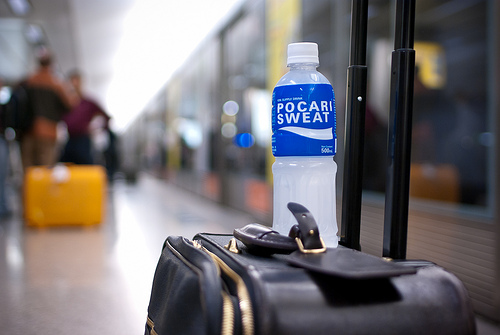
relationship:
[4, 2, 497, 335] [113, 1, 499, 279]
train station with train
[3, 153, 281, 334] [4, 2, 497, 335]
platform at train station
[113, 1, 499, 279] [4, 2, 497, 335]
train at train station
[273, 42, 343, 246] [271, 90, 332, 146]
water bottle with a label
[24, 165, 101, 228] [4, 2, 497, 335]
suitcase at train station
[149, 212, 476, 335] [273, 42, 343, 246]
suitcase with water bottle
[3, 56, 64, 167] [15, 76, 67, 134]
man with a jacket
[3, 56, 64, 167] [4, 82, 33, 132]
man carrying backpack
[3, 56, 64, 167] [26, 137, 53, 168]
man wearing pants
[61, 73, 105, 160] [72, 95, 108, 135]
person wearing shirt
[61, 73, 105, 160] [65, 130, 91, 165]
person wearing pants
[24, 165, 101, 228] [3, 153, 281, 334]
suitcase sitting on platform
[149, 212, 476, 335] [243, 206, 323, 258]
suitcase with handle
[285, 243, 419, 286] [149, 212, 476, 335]
tag on suitcase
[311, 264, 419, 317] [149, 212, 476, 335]
shadow on suitcase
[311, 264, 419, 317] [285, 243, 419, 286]
shadow from tag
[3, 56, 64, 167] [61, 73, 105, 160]
man talking to person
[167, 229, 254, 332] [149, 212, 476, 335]
zippers on suitcase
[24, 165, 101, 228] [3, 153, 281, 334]
suitcase on platform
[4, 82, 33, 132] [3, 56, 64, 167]
backpack on man